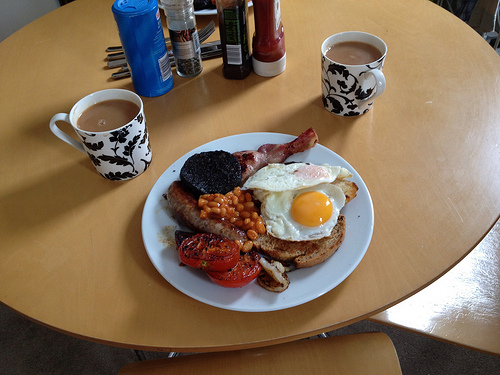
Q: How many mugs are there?
A: Two.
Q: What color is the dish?
A: White.